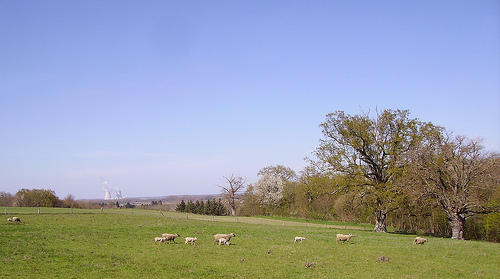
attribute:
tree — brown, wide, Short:
[378, 130, 496, 240]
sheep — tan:
[407, 226, 435, 255]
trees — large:
[222, 103, 498, 241]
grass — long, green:
[3, 203, 497, 276]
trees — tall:
[177, 196, 232, 219]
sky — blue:
[2, 1, 497, 208]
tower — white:
[98, 181, 115, 217]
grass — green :
[70, 233, 132, 263]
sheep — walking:
[148, 225, 353, 246]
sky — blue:
[5, 5, 484, 95]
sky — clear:
[8, 13, 474, 74]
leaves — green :
[383, 127, 403, 143]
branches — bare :
[448, 152, 478, 193]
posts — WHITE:
[11, 210, 374, 222]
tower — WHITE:
[102, 185, 111, 204]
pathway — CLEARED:
[138, 214, 331, 226]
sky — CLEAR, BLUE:
[17, 10, 479, 180]